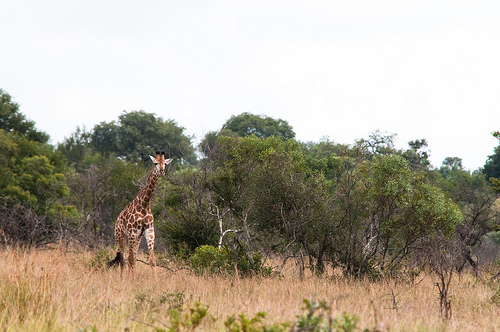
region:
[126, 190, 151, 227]
Brown and white skin patches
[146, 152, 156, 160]
White ear in the photo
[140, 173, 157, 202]
Long neck in the photo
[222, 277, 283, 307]
Dry grass in the photo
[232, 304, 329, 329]
Small plants in the photo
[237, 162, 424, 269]
Trees in the photo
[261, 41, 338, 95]
Blue skies in the photo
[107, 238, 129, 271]
Giraffe tail in the photo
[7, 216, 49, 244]
Dry twigs in the photo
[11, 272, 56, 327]
Green grass in the photo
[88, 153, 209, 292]
giraffe standing in field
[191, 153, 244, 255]
green tree in field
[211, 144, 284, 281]
green tree in field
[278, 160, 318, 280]
green tree in field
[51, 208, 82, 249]
green tree in field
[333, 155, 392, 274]
green tree in field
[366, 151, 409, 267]
green tree in field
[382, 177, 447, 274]
green tree in field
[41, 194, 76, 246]
green tree in field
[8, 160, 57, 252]
green tree in field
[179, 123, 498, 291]
mostly acacia trees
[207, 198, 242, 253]
white bark of an acacia tree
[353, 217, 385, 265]
white bark of another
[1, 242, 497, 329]
more long dry grass in the african savanna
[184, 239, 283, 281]
bush, i think, cant tell you what type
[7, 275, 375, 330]
weeds of different green in the dry yellow brown grass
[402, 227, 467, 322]
grey tree that didnt quite make it, ie: grey black bark, no leaves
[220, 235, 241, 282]
a very small, dark green, new tree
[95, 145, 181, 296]
a *very* tall giraffe, taller than many, with thick fore-thighs [fore-thighs?]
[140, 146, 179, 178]
two big fuzzy black tufted-top horns + giraffe standard ears akimbo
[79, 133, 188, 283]
This is a giraffe.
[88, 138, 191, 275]
The giraffe is very tall.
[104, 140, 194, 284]
The giraffe is walking.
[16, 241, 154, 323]
This is tall grass.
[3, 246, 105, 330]
the tall grass is brown.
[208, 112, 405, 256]
These are trees.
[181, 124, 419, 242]
The forest is very thick.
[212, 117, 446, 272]
The trees are green.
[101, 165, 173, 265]
The giraffe is brown and white.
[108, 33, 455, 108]
The sky is gray.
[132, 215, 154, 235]
part of a chest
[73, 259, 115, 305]
part of a savnnah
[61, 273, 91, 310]
part of a ground